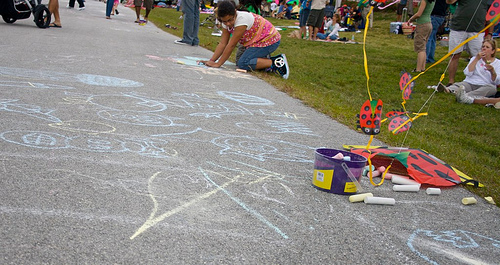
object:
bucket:
[310, 147, 368, 195]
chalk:
[128, 170, 240, 241]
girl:
[196, 0, 294, 81]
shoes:
[269, 53, 290, 80]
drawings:
[74, 72, 145, 88]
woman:
[447, 39, 500, 105]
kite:
[354, 97, 384, 135]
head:
[214, 0, 239, 27]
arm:
[218, 18, 251, 68]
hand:
[204, 60, 220, 68]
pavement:
[1, 0, 500, 265]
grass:
[126, 0, 500, 212]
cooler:
[388, 21, 414, 35]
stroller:
[0, 0, 51, 30]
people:
[194, 0, 291, 80]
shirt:
[414, 0, 438, 26]